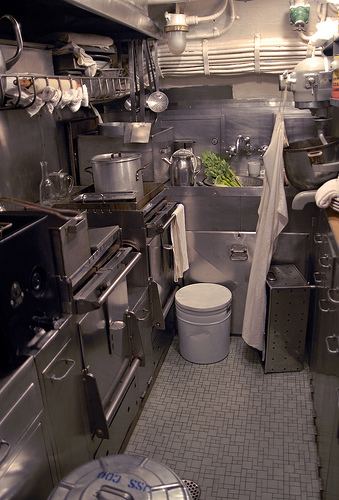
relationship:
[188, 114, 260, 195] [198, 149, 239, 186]
sink with leaves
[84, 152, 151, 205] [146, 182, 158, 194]
pot on table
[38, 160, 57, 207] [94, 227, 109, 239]
container on table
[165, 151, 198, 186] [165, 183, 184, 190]
jug on table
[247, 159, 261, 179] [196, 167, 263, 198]
cup on sink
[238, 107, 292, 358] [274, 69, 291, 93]
apron on mixer nozzle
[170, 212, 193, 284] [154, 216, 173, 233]
towel on handle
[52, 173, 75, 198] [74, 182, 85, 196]
pitcher on counter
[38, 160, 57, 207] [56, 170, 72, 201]
container on or side of vase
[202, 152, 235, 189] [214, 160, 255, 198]
vegetables are in sink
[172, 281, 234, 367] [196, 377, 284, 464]
container on floor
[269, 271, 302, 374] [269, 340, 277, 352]
box has holes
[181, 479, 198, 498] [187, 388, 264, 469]
drain in floor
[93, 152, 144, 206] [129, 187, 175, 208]
pot on stove top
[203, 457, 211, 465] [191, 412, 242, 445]
tile on floor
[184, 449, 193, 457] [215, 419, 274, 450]
tile on floor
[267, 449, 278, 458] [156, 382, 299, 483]
white tile on a floor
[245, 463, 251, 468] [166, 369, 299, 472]
white tile on a floor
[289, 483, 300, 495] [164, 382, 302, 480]
white tile on a floor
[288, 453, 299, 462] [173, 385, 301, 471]
white tile on a floor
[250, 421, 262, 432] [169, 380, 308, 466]
white tile on a floor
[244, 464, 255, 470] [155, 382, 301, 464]
white tile on a floor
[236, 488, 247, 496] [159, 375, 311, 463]
white tile on a floor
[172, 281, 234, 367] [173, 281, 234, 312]
container with cover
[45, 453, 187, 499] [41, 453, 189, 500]
silver trashcan with trashcan lid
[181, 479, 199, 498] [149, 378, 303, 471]
drain in floor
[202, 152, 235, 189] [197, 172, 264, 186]
vegetables in sink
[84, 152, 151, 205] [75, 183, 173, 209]
pot on stove top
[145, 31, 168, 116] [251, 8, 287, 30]
utensils hanging from wall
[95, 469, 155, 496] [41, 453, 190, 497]
blue writing on trashcan lid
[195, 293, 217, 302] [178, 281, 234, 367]
white cylindrical container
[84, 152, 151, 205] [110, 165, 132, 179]
pot color silver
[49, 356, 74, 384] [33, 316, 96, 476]
handle on a counter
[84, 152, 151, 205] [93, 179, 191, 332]
pot sitting stove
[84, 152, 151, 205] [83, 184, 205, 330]
pot sitting oven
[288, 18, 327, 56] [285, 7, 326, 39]
light with cover